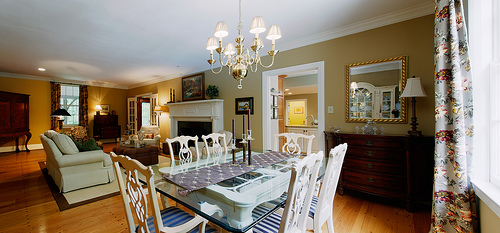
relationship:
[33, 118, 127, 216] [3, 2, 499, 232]
sofa in room